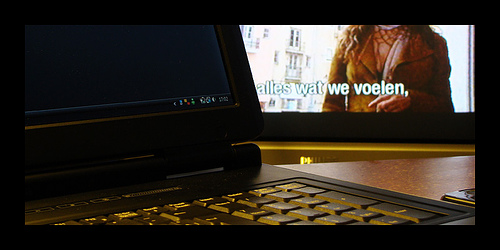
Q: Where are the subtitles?
A: On the tv screen.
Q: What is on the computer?
A: A black keyboard.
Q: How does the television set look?
A: It is on.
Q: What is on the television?
A: A woman in front of a building.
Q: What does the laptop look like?
A: It is black.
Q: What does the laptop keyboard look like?
A: It is black.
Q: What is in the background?
A: A television.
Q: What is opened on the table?
A: A black laptop.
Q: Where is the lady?
A: On tv.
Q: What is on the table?
A: A laptop.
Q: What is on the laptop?
A: A keyboard.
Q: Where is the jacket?
A: On tv.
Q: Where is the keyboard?
A: On the laptop.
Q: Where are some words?
A: On the tv.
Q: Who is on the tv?
A: A lady.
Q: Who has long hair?
A: The lady.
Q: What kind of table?
A: Wood.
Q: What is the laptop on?
A: A desk.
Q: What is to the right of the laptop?
A: A book.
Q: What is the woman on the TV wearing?
A: A green jacket.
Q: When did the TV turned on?
A: Earlier.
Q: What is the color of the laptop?
A: Black.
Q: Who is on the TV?
A: A woman.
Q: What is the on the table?
A: A laptop.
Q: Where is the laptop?
A: On the table.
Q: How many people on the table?
A: Zero.